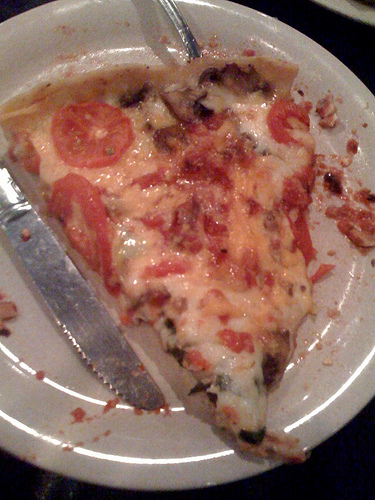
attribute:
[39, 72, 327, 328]
pizza — white, cooked, cheesy, thin, small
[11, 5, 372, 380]
plate — white, metal, round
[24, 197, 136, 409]
knife — silver, grey, metal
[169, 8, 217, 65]
fork — silver